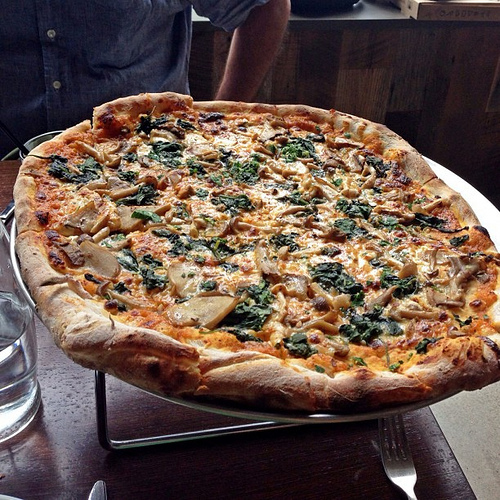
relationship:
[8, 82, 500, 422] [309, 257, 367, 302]
pizza has spinach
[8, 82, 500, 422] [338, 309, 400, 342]
pizza has spinach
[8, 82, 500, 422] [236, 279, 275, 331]
pizza has spinach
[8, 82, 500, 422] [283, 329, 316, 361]
pizza has spinach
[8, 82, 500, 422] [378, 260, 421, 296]
pizza has spinach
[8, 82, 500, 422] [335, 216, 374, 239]
pizza has spinach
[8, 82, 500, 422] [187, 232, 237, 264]
pizza has spinach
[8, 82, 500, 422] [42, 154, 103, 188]
pizza has spinach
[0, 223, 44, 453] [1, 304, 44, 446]
container has water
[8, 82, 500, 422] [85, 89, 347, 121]
pizza has dry crust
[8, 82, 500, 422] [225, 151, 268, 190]
pizza has spinach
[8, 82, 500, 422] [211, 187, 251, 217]
pizza has spinach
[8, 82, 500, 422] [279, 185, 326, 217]
pizza has spinach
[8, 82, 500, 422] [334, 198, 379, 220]
pizza has spinach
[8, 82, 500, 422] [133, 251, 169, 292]
pizza has spinach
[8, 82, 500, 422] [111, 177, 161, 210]
pizza has spinach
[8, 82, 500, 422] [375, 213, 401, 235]
pizza has spinach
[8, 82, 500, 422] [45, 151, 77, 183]
pizza has spinach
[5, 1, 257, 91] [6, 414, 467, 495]
man sitting at table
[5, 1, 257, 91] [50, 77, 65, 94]
shirt has button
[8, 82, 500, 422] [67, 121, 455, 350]
pizza has toppings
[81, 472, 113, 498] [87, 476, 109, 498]
knife seen top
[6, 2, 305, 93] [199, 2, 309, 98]
man seen forearm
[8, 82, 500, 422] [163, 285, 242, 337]
pizza has mushroom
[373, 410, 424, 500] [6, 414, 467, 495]
fork on a table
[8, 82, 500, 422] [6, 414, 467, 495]
pizza over brown table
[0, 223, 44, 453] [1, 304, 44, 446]
glass of water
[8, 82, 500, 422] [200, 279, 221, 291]
pizza has spinach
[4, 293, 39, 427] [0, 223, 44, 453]
liquid in container